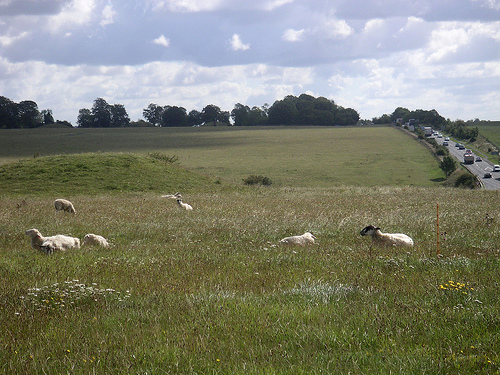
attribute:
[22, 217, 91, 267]
sheep — grazing, black, white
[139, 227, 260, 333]
grass — cut, green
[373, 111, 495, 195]
highway — in background, two-lane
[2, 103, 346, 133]
trees — in distance, green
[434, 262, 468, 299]
flowers — yellow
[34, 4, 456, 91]
sky — cloudy, bright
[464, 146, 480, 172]
truck — white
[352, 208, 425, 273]
sheep — black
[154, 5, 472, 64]
clouds — white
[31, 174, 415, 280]
sheep — lying down, together, walking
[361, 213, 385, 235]
head — black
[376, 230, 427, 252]
body — white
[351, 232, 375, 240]
face — black